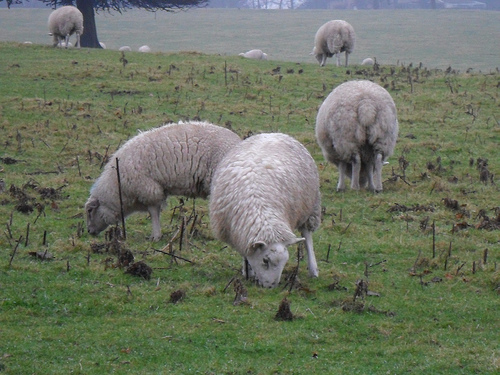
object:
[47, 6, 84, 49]
sheep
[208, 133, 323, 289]
sheep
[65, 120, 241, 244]
sheep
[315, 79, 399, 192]
sheep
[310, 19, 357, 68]
sheep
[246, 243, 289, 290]
head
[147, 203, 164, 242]
leg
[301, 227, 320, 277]
leg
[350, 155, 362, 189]
leg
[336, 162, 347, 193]
leg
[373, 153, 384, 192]
leg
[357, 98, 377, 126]
tail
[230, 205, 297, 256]
neck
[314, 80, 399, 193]
back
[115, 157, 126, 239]
stem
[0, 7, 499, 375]
ground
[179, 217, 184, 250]
stem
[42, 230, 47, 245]
stem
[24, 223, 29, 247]
stem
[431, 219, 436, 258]
stem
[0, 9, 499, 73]
lower elevation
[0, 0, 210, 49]
tree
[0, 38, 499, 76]
edge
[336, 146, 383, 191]
underside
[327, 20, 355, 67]
backside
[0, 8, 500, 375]
grass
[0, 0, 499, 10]
hill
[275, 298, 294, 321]
plant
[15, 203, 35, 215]
plant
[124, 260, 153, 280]
plant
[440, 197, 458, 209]
plant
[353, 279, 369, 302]
plant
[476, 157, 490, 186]
plant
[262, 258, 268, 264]
eye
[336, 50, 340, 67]
leg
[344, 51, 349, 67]
leg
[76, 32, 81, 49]
leg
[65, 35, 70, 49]
leg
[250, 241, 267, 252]
ear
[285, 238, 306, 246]
ear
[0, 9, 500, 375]
field